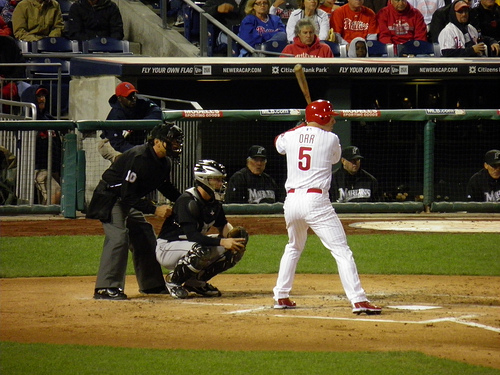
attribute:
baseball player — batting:
[271, 98, 387, 332]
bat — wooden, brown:
[291, 61, 313, 100]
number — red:
[297, 146, 314, 177]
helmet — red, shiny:
[301, 99, 341, 127]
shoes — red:
[268, 293, 382, 318]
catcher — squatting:
[160, 159, 251, 304]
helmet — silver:
[193, 157, 229, 186]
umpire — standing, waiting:
[90, 115, 177, 308]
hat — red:
[113, 77, 139, 101]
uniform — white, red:
[277, 126, 363, 302]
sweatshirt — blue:
[107, 103, 155, 143]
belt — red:
[283, 186, 335, 194]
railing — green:
[349, 102, 498, 221]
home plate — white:
[384, 301, 446, 314]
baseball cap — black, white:
[245, 143, 271, 163]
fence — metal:
[3, 97, 41, 204]